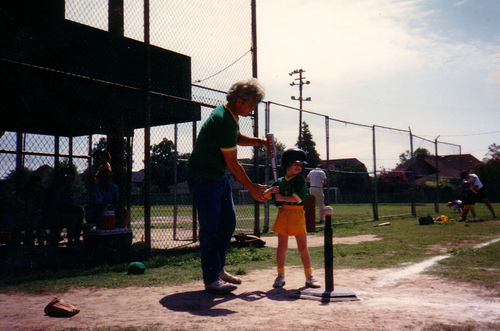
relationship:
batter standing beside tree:
[262, 133, 321, 289] [288, 121, 325, 235]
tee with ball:
[315, 203, 362, 305] [319, 202, 337, 217]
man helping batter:
[201, 82, 259, 281] [255, 144, 322, 296]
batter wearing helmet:
[255, 142, 327, 300] [261, 122, 324, 188]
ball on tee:
[319, 202, 337, 217] [283, 213, 363, 304]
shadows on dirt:
[153, 271, 379, 323] [114, 280, 491, 329]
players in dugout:
[0, 148, 130, 244] [10, 10, 198, 301]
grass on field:
[404, 222, 411, 255] [139, 201, 482, 306]